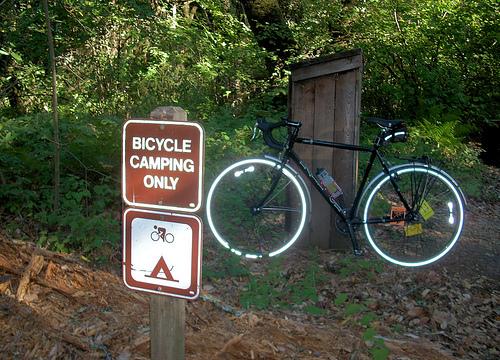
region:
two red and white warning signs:
[115, 114, 214, 306]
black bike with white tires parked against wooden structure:
[205, 107, 470, 279]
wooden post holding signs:
[146, 103, 196, 353]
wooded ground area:
[6, 228, 461, 358]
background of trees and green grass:
[12, 4, 492, 246]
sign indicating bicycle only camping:
[122, 117, 200, 215]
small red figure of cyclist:
[146, 224, 176, 245]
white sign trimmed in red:
[124, 218, 201, 293]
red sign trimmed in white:
[120, 118, 205, 209]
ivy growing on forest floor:
[236, 263, 422, 348]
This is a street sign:
[63, 106, 203, 304]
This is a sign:
[104, 89, 206, 330]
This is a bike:
[203, 126, 496, 311]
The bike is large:
[287, 121, 429, 247]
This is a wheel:
[190, 149, 314, 244]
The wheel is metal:
[200, 173, 347, 289]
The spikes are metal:
[243, 205, 290, 244]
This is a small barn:
[242, 75, 461, 185]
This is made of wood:
[278, 89, 330, 156]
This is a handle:
[250, 123, 302, 155]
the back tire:
[432, 250, 447, 260]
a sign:
[117, 120, 207, 222]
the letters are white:
[123, 132, 195, 210]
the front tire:
[225, 240, 244, 255]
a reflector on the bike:
[233, 163, 264, 177]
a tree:
[46, 101, 75, 201]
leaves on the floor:
[388, 292, 496, 348]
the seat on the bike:
[365, 116, 402, 132]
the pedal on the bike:
[351, 244, 376, 259]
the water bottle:
[312, 163, 351, 203]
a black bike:
[196, 88, 493, 288]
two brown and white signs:
[114, 108, 221, 323]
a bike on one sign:
[147, 217, 178, 241]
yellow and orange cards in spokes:
[378, 189, 449, 249]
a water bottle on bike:
[305, 160, 362, 206]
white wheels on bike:
[214, 151, 464, 276]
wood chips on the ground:
[15, 242, 356, 359]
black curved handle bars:
[253, 108, 305, 170]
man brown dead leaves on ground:
[256, 237, 499, 357]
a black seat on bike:
[346, 105, 426, 138]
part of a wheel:
[379, 220, 388, 244]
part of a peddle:
[353, 199, 358, 208]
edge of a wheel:
[250, 165, 290, 202]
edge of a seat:
[380, 130, 387, 147]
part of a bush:
[223, 148, 238, 175]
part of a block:
[320, 86, 340, 129]